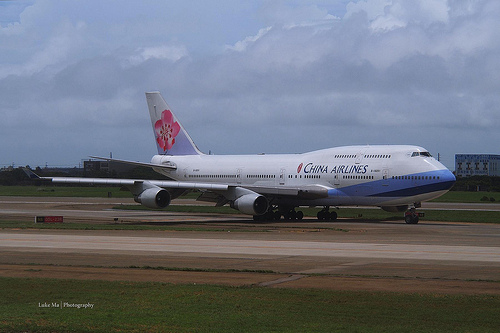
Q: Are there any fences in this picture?
A: No, there are no fences.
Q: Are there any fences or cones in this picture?
A: No, there are no fences or cones.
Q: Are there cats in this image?
A: No, there are no cats.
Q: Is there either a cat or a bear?
A: No, there are no cats or bears.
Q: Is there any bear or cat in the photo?
A: No, there are no cats or bears.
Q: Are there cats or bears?
A: No, there are no cats or bears.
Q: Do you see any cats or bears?
A: No, there are no cats or bears.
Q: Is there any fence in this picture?
A: No, there are no fences.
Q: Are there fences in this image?
A: No, there are no fences.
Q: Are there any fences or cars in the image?
A: No, there are no fences or cars.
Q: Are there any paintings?
A: No, there are no paintings.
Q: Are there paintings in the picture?
A: No, there are no paintings.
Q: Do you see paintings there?
A: No, there are no paintings.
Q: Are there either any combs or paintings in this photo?
A: No, there are no paintings or combs.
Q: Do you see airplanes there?
A: Yes, there is an airplane.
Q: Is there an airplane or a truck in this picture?
A: Yes, there is an airplane.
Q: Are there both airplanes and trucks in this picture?
A: No, there is an airplane but no trucks.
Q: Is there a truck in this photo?
A: No, there are no trucks.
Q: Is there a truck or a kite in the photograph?
A: No, there are no trucks or kites.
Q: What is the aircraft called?
A: The aircraft is an airplane.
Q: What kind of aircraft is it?
A: The aircraft is an airplane.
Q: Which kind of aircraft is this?
A: This is an airplane.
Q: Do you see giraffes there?
A: No, there are no giraffes.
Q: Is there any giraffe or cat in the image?
A: No, there are no giraffes or cats.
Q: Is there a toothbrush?
A: No, there are no toothbrushes.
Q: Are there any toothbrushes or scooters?
A: No, there are no toothbrushes or scooters.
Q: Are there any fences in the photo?
A: No, there are no fences.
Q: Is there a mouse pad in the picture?
A: No, there are no mouse pads.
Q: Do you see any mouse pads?
A: No, there are no mouse pads.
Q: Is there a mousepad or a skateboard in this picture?
A: No, there are no mouse pads or skateboards.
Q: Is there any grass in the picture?
A: Yes, there is grass.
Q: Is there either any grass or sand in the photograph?
A: Yes, there is grass.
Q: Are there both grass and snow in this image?
A: No, there is grass but no snow.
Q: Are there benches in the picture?
A: No, there are no benches.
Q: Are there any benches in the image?
A: No, there are no benches.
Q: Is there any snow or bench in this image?
A: No, there are no benches or snow.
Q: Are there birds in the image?
A: No, there are no birds.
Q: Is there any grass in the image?
A: Yes, there is grass.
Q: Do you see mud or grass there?
A: Yes, there is grass.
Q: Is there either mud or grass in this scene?
A: Yes, there is grass.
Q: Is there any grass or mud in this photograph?
A: Yes, there is grass.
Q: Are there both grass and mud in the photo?
A: No, there is grass but no mud.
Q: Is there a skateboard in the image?
A: No, there are no skateboards.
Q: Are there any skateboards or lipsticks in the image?
A: No, there are no skateboards or lipsticks.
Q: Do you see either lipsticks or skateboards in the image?
A: No, there are no skateboards or lipsticks.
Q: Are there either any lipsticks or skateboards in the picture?
A: No, there are no skateboards or lipsticks.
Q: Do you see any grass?
A: Yes, there is grass.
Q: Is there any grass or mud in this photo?
A: Yes, there is grass.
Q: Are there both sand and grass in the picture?
A: No, there is grass but no sand.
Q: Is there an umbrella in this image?
A: No, there are no umbrellas.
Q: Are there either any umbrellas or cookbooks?
A: No, there are no umbrellas or cookbooks.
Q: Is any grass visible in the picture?
A: Yes, there is grass.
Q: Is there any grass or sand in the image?
A: Yes, there is grass.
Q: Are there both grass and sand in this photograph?
A: No, there is grass but no sand.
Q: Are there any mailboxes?
A: No, there are no mailboxes.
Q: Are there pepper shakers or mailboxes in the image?
A: No, there are no mailboxes or pepper shakers.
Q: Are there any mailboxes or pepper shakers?
A: No, there are no mailboxes or pepper shakers.